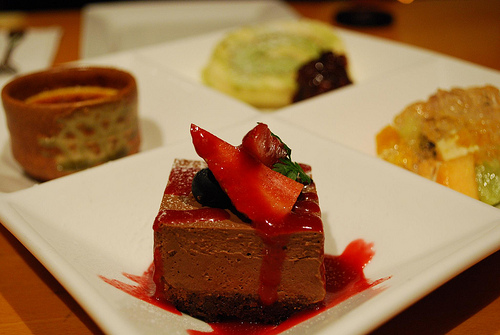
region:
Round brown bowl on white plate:
[0, 62, 148, 178]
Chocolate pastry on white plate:
[150, 150, 329, 310]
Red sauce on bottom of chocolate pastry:
[105, 219, 392, 333]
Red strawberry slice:
[189, 117, 308, 229]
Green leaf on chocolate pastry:
[274, 137, 313, 194]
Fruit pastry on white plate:
[374, 75, 499, 207]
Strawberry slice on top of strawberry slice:
[237, 116, 287, 163]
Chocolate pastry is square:
[151, 154, 327, 311]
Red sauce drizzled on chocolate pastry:
[149, 150, 329, 301]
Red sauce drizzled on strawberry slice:
[185, 112, 230, 170]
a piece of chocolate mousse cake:
[154, 119, 325, 314]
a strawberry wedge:
[187, 121, 302, 220]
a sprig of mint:
[276, 158, 315, 184]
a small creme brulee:
[1, 63, 160, 180]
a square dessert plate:
[4, 109, 499, 331]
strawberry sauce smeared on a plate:
[323, 247, 378, 297]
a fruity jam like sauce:
[293, 48, 353, 94]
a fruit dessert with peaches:
[375, 85, 497, 196]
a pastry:
[200, 22, 331, 95]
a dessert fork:
[1, 19, 26, 86]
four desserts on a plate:
[29, 15, 499, 334]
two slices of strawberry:
[215, 123, 302, 208]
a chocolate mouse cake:
[147, 155, 340, 324]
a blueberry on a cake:
[188, 162, 228, 213]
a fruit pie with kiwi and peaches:
[384, 80, 499, 193]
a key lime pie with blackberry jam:
[201, 13, 355, 103]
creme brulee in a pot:
[0, 67, 157, 172]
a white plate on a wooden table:
[7, 182, 92, 333]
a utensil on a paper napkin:
[3, 20, 61, 70]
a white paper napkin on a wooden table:
[34, 23, 64, 65]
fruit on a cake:
[187, 104, 315, 216]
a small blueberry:
[186, 163, 231, 210]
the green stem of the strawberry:
[272, 156, 309, 184]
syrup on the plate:
[330, 212, 392, 310]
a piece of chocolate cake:
[129, 127, 342, 332]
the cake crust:
[149, 279, 318, 328]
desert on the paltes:
[0, 19, 497, 318]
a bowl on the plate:
[3, 55, 151, 186]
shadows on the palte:
[137, 94, 169, 167]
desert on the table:
[115, 12, 492, 327]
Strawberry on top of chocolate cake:
[187, 121, 307, 224]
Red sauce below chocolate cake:
[97, 235, 391, 333]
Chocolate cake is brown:
[147, 153, 333, 306]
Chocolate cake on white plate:
[150, 150, 325, 307]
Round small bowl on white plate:
[0, 60, 140, 175]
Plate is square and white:
[0, 100, 497, 330]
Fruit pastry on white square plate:
[371, 77, 498, 205]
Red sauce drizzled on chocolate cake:
[152, 156, 322, 303]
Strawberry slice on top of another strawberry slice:
[244, 122, 291, 167]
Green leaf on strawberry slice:
[275, 153, 312, 185]